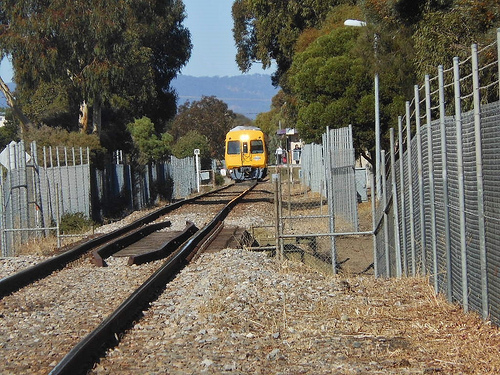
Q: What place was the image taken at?
A: It was taken at the street.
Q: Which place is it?
A: It is a street.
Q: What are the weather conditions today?
A: It is clear.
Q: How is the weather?
A: It is clear.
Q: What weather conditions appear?
A: It is clear.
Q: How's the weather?
A: It is clear.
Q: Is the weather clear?
A: Yes, it is clear.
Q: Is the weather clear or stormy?
A: It is clear.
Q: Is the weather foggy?
A: No, it is clear.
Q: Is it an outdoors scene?
A: Yes, it is outdoors.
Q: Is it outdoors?
A: Yes, it is outdoors.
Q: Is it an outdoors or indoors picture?
A: It is outdoors.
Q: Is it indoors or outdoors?
A: It is outdoors.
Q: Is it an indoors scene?
A: No, it is outdoors.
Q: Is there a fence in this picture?
A: Yes, there is a fence.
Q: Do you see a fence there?
A: Yes, there is a fence.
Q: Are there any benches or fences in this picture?
A: Yes, there is a fence.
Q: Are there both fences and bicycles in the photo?
A: No, there is a fence but no bicycles.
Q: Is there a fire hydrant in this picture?
A: No, there are no fire hydrants.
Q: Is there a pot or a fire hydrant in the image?
A: No, there are no fire hydrants or pots.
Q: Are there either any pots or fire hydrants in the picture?
A: No, there are no fire hydrants or pots.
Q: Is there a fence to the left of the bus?
A: Yes, there is a fence to the left of the bus.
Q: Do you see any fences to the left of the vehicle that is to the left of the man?
A: Yes, there is a fence to the left of the bus.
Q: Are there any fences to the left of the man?
A: Yes, there is a fence to the left of the man.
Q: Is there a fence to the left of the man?
A: Yes, there is a fence to the left of the man.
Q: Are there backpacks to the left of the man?
A: No, there is a fence to the left of the man.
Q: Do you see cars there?
A: No, there are no cars.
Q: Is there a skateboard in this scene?
A: No, there are no skateboards.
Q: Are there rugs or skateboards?
A: No, there are no skateboards or rugs.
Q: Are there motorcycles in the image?
A: No, there are no motorcycles.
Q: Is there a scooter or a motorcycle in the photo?
A: No, there are no motorcycles or scooters.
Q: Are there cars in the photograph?
A: No, there are no cars.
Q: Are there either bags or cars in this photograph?
A: No, there are no cars or bags.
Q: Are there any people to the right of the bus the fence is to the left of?
A: Yes, there are people to the right of the bus.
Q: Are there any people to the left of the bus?
A: No, the people are to the right of the bus.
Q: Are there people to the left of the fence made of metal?
A: Yes, there are people to the left of the fence.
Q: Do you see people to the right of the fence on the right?
A: No, the people are to the left of the fence.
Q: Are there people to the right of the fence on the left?
A: Yes, there are people to the right of the fence.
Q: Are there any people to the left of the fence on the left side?
A: No, the people are to the right of the fence.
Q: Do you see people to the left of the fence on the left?
A: No, the people are to the right of the fence.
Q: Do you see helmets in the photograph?
A: No, there are no helmets.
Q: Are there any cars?
A: No, there are no cars.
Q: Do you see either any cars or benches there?
A: No, there are no cars or benches.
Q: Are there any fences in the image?
A: Yes, there is a fence.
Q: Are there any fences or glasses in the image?
A: Yes, there is a fence.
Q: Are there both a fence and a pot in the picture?
A: No, there is a fence but no pots.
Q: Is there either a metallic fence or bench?
A: Yes, there is a metal fence.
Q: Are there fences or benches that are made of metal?
A: Yes, the fence is made of metal.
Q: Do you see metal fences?
A: Yes, there is a metal fence.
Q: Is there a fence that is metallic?
A: Yes, there is a fence that is metallic.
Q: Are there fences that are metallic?
A: Yes, there is a fence that is metallic.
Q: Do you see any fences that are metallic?
A: Yes, there is a fence that is metallic.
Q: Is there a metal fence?
A: Yes, there is a fence that is made of metal.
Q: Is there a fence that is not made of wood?
A: Yes, there is a fence that is made of metal.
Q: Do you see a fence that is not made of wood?
A: Yes, there is a fence that is made of metal.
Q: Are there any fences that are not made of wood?
A: Yes, there is a fence that is made of metal.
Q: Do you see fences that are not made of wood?
A: Yes, there is a fence that is made of metal.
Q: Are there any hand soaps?
A: No, there are no hand soaps.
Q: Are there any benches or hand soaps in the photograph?
A: No, there are no hand soaps or benches.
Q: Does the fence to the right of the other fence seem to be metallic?
A: Yes, the fence is metallic.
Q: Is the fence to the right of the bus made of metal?
A: Yes, the fence is made of metal.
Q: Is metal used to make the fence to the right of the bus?
A: Yes, the fence is made of metal.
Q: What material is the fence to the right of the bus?
A: The fence is made of metal.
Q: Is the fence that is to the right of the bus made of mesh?
A: No, the fence is made of metal.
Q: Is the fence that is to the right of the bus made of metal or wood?
A: The fence is made of metal.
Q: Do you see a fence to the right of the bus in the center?
A: Yes, there is a fence to the right of the bus.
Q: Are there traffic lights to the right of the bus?
A: No, there is a fence to the right of the bus.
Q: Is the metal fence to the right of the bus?
A: Yes, the fence is to the right of the bus.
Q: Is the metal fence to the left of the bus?
A: No, the fence is to the right of the bus.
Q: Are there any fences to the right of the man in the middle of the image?
A: Yes, there is a fence to the right of the man.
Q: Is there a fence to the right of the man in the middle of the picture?
A: Yes, there is a fence to the right of the man.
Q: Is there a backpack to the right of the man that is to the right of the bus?
A: No, there is a fence to the right of the man.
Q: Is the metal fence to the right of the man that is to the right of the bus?
A: Yes, the fence is to the right of the man.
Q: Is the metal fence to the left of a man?
A: No, the fence is to the right of a man.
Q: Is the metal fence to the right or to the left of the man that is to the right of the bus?
A: The fence is to the right of the man.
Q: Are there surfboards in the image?
A: No, there are no surfboards.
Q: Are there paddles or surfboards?
A: No, there are no surfboards or paddles.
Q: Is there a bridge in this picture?
A: Yes, there is a bridge.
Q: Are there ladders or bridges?
A: Yes, there is a bridge.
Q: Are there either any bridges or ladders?
A: Yes, there is a bridge.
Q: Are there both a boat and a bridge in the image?
A: No, there is a bridge but no boats.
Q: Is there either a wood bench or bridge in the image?
A: Yes, there is a wood bridge.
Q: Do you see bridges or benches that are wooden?
A: Yes, the bridge is wooden.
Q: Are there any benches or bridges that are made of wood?
A: Yes, the bridge is made of wood.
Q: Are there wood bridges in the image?
A: Yes, there is a wood bridge.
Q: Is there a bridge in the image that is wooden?
A: Yes, there is a bridge that is wooden.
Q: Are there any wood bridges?
A: Yes, there is a bridge that is made of wood.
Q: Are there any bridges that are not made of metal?
A: Yes, there is a bridge that is made of wood.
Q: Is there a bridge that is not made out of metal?
A: Yes, there is a bridge that is made of wood.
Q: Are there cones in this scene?
A: No, there are no cones.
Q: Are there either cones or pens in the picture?
A: No, there are no cones or pens.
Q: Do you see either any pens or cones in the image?
A: No, there are no cones or pens.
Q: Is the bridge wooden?
A: Yes, the bridge is wooden.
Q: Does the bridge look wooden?
A: Yes, the bridge is wooden.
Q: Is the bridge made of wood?
A: Yes, the bridge is made of wood.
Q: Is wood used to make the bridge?
A: Yes, the bridge is made of wood.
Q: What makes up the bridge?
A: The bridge is made of wood.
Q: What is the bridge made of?
A: The bridge is made of wood.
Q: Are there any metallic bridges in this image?
A: No, there is a bridge but it is wooden.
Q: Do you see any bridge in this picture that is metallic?
A: No, there is a bridge but it is wooden.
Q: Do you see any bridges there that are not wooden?
A: No, there is a bridge but it is wooden.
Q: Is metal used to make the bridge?
A: No, the bridge is made of wood.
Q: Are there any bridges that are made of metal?
A: No, there is a bridge but it is made of wood.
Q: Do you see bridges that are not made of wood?
A: No, there is a bridge but it is made of wood.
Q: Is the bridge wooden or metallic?
A: The bridge is wooden.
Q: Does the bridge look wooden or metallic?
A: The bridge is wooden.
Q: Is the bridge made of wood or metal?
A: The bridge is made of wood.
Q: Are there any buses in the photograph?
A: Yes, there is a bus.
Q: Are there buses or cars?
A: Yes, there is a bus.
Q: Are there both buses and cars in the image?
A: No, there is a bus but no cars.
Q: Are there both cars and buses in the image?
A: No, there is a bus but no cars.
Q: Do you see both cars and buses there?
A: No, there is a bus but no cars.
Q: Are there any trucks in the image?
A: No, there are no trucks.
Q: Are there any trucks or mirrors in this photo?
A: No, there are no trucks or mirrors.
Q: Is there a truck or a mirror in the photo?
A: No, there are no trucks or mirrors.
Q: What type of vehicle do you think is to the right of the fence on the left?
A: The vehicle is a bus.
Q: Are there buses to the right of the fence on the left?
A: Yes, there is a bus to the right of the fence.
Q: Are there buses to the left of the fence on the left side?
A: No, the bus is to the right of the fence.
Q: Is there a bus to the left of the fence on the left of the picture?
A: No, the bus is to the right of the fence.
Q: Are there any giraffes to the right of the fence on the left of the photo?
A: No, there is a bus to the right of the fence.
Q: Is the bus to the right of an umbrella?
A: No, the bus is to the right of the fence.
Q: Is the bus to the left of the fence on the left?
A: No, the bus is to the right of the fence.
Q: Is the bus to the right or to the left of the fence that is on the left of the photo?
A: The bus is to the right of the fence.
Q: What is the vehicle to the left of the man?
A: The vehicle is a bus.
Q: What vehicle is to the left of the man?
A: The vehicle is a bus.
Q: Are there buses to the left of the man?
A: Yes, there is a bus to the left of the man.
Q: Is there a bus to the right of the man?
A: No, the bus is to the left of the man.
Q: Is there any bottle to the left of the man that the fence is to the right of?
A: No, there is a bus to the left of the man.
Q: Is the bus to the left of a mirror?
A: No, the bus is to the left of a man.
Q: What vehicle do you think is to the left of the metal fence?
A: The vehicle is a bus.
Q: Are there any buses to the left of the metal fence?
A: Yes, there is a bus to the left of the fence.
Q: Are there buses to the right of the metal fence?
A: No, the bus is to the left of the fence.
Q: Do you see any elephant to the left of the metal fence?
A: No, there is a bus to the left of the fence.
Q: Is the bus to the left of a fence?
A: Yes, the bus is to the left of a fence.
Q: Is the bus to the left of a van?
A: No, the bus is to the left of a fence.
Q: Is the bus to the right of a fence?
A: No, the bus is to the left of a fence.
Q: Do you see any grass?
A: Yes, there is grass.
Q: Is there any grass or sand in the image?
A: Yes, there is grass.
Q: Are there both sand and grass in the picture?
A: No, there is grass but no sand.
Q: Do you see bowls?
A: No, there are no bowls.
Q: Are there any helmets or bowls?
A: No, there are no bowls or helmets.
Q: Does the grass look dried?
A: Yes, the grass is dried.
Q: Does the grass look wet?
A: No, the grass is dried.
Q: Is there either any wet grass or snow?
A: No, there is grass but it is dried.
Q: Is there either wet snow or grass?
A: No, there is grass but it is dried.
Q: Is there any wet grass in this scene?
A: No, there is grass but it is dried.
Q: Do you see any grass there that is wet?
A: No, there is grass but it is dried.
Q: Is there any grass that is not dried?
A: No, there is grass but it is dried.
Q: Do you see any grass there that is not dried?
A: No, there is grass but it is dried.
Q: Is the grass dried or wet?
A: The grass is dried.